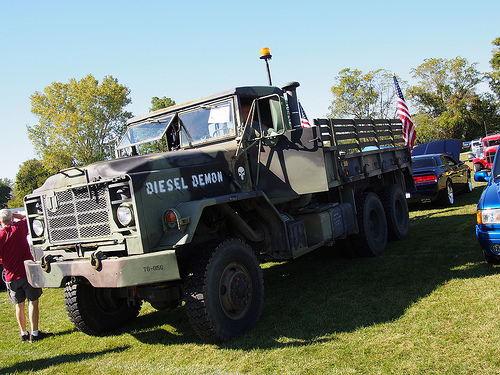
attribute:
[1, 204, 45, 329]
man — sitting